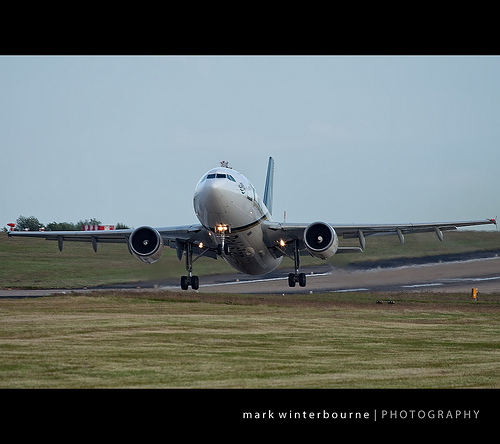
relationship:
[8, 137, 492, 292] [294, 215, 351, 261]
plane has engine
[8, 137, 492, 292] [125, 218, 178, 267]
plane has engine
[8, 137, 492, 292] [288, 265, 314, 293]
plane has wheel